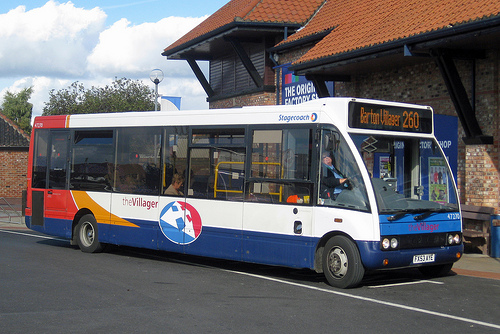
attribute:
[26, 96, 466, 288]
bus — red, blue, white, parked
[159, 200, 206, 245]
arrows — red, blue, white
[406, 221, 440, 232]
letters — red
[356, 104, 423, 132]
words — orange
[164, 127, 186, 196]
window — side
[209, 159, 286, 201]
handrail — yellow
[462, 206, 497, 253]
bench — brown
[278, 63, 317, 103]
sign — blue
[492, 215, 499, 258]
trashcan — blue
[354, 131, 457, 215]
window — long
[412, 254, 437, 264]
license plate — white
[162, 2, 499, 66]
roof — part, red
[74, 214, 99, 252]
wheel — gray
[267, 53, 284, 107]
pipe — part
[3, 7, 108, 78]
cloud — part